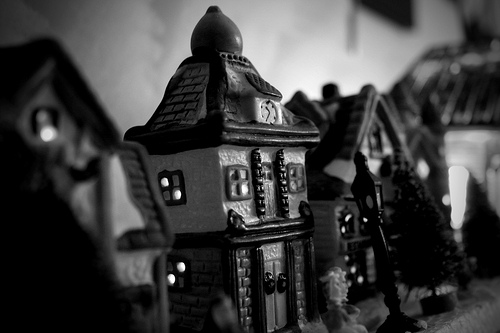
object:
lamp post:
[351, 154, 427, 332]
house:
[124, 3, 340, 331]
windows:
[223, 162, 253, 201]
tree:
[387, 151, 465, 315]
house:
[307, 82, 415, 305]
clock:
[259, 98, 284, 127]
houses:
[0, 36, 173, 333]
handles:
[265, 270, 277, 295]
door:
[264, 260, 293, 332]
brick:
[190, 281, 213, 298]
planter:
[423, 286, 453, 318]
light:
[160, 177, 185, 203]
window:
[157, 169, 186, 207]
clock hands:
[265, 111, 270, 122]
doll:
[205, 295, 241, 332]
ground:
[322, 275, 500, 332]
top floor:
[133, 134, 309, 223]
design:
[266, 270, 287, 295]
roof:
[142, 52, 301, 128]